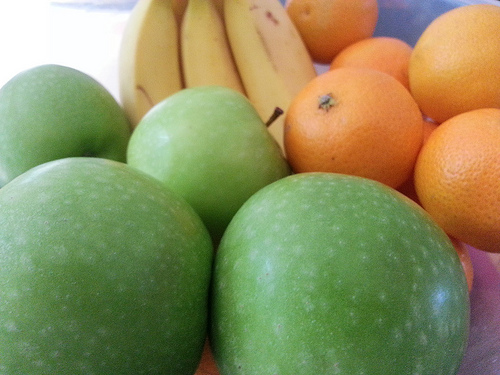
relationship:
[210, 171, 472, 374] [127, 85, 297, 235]
apple next to apple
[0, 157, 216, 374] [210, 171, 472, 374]
apple next to apple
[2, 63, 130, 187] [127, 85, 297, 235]
apple next to apple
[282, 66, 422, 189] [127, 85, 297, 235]
orange next to apple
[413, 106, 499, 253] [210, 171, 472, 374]
orange next to apple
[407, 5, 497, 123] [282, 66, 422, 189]
orange next to orange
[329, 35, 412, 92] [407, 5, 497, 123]
orange next to orange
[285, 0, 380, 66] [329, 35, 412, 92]
orange next to orange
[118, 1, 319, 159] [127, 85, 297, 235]
bananas behind apple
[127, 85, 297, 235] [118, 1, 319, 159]
apple near bananas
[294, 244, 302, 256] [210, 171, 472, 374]
spot on surface of apple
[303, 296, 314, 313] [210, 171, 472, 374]
spot on surface of apple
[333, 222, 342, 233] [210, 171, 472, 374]
spot on surface of apple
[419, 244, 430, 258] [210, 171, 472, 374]
spot on surface of apple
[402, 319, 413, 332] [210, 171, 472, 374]
spot on surface of apple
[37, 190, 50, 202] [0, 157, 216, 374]
spot on surface of apple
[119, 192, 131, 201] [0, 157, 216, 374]
spot on surface of apple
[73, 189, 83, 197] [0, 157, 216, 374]
spot on surface of apple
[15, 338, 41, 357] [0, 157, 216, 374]
spot on surface of apple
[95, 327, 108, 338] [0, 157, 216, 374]
spot on surface of apple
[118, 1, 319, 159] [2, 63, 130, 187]
bananas near apple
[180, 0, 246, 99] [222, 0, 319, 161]
banana next to banana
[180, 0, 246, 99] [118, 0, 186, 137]
banana next to bananas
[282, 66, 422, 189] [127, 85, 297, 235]
orange near apple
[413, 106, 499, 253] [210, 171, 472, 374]
orange near apple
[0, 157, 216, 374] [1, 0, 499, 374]
apple on top of surface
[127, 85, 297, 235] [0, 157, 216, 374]
apple next to apple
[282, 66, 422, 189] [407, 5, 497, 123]
orange part of orange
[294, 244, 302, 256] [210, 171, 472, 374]
spot on top of apple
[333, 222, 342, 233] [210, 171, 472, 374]
spot on top of apple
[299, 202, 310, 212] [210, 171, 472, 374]
spot on top of apple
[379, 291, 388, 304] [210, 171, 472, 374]
spot on top of apple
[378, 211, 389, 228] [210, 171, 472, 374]
spot on top of apple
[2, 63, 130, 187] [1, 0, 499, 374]
apple on top of surface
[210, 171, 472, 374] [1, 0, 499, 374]
apple on top of surface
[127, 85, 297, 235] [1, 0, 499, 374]
apple on top of surface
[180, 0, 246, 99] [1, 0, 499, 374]
banana on top of surface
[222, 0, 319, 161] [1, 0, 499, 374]
banana on top of surface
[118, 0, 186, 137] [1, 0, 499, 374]
bananas on top of surface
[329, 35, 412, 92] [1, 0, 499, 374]
orange on top of surface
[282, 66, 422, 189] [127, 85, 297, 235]
orange to right of apple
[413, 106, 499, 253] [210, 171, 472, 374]
orange to right of apple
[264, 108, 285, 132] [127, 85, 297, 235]
stem attached to apple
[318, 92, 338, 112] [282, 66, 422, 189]
stem located on orange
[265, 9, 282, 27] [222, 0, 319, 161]
bruise visible on banana